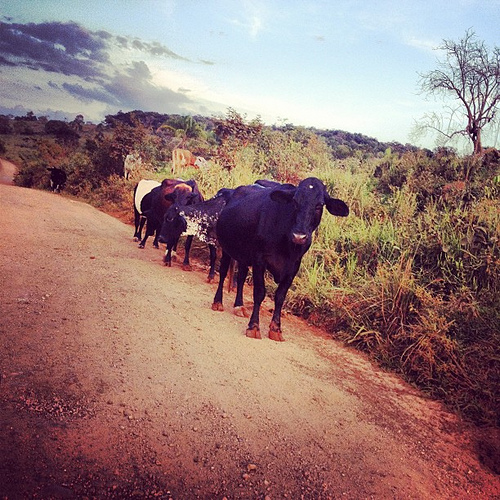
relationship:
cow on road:
[165, 200, 221, 278] [142, 282, 219, 485]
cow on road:
[211, 177, 349, 341] [1, 158, 497, 498]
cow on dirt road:
[211, 177, 349, 341] [0, 156, 500, 498]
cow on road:
[165, 179, 282, 291] [70, 338, 380, 497]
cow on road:
[165, 179, 282, 291] [1, 158, 497, 498]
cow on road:
[127, 170, 177, 227] [1, 158, 497, 498]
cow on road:
[211, 177, 349, 341] [13, 257, 233, 464]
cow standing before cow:
[211, 177, 349, 341] [153, 189, 238, 277]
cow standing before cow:
[211, 177, 349, 341] [130, 170, 200, 240]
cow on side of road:
[211, 177, 349, 341] [4, 340, 439, 494]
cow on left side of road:
[211, 177, 349, 341] [1, 158, 497, 498]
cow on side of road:
[211, 177, 349, 341] [19, 185, 275, 465]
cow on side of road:
[165, 179, 282, 291] [19, 185, 275, 465]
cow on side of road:
[136, 177, 204, 272] [19, 185, 275, 465]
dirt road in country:
[0, 156, 500, 498] [20, 7, 481, 309]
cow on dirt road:
[211, 177, 349, 341] [10, 275, 434, 463]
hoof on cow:
[243, 322, 260, 342] [211, 177, 349, 341]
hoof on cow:
[265, 326, 284, 343] [211, 177, 349, 341]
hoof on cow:
[232, 305, 249, 321] [211, 177, 349, 341]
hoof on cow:
[209, 295, 226, 315] [211, 177, 349, 341]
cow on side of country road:
[211, 177, 349, 341] [10, 213, 128, 498]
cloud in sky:
[1, 14, 246, 116] [3, 0, 488, 152]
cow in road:
[211, 177, 349, 341] [18, 205, 397, 480]